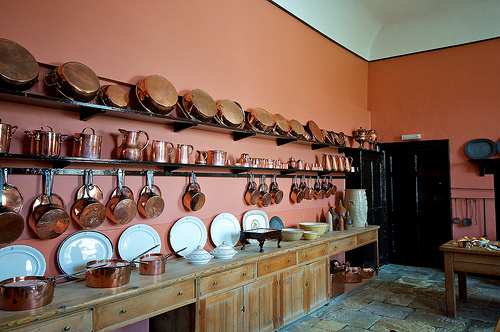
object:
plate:
[117, 224, 162, 268]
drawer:
[197, 264, 255, 298]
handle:
[243, 272, 247, 275]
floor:
[303, 294, 497, 331]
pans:
[28, 167, 205, 241]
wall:
[2, 1, 406, 262]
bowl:
[299, 223, 328, 237]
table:
[1, 225, 383, 331]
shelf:
[0, 60, 369, 177]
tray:
[239, 227, 282, 253]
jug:
[344, 188, 369, 227]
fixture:
[402, 134, 421, 141]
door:
[387, 140, 447, 269]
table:
[437, 236, 500, 317]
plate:
[269, 216, 285, 239]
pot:
[133, 174, 165, 220]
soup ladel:
[452, 195, 479, 227]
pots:
[52, 259, 139, 288]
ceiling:
[286, 1, 500, 56]